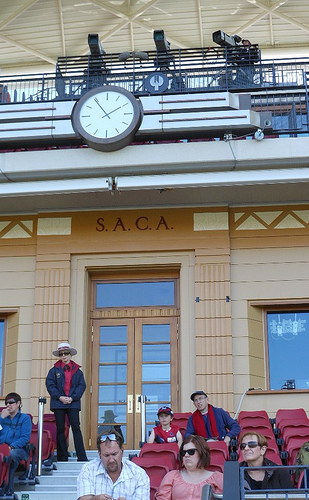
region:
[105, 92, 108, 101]
black line representing number on clock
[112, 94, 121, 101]
black line representing number on clock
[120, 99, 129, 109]
black line representing number on clock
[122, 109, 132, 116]
black line representing number on clock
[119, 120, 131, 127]
black line representing number on clock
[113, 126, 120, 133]
black line representing number on clock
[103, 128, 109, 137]
black line representing number on clock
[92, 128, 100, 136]
black line representing number on clock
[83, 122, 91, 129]
black line representing number on clock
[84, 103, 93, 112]
black line representing number on clock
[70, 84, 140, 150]
clock with a white face and brown numbers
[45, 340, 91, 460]
woman wearing a white hat and sunglasses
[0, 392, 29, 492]
man wearing sunglasses and a blue jacket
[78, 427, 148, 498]
man with sunglasses on his head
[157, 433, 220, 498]
woman with a pink shirt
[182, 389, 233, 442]
man wearing a blue jacket and red scarf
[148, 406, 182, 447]
child wearing a hat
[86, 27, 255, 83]
three television cameras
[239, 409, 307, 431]
red seats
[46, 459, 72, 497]
stairs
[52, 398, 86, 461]
THE WOMAN IS WEARING BLACK PANTS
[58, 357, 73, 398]
THE WOMAN IS WEARING A RED SHIRT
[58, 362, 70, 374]
THE WOMAN IS WEARING A BLACK TIE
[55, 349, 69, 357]
THE WOMAN IS WEARING DARK SUNGLASSES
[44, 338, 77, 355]
THE WOMAN IS WEARING A HAT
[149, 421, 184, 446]
THE KID IS WEARING A RED SHIRT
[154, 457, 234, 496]
THE WOMAN IS WEARING A PINK SHIRT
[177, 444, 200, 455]
THE WOMAN IS WEARING SUNGLASSES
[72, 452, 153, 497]
THE MAN IS WEARING A WHITE SHIRT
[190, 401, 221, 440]
THE MAN IS WEARING A RED SCARF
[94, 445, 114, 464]
eye of a person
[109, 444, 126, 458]
eye of a person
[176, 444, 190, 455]
eye of a person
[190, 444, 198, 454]
eye of a person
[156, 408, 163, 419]
eye of a person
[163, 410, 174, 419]
eye of a person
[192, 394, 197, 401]
eye of a person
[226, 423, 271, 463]
head of a person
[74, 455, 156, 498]
Man wearing a shirt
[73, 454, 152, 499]
Man is wearing a white shirt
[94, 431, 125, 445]
Sunglasses on man's head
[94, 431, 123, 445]
Sunglasses are on man's head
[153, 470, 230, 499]
Woman wearing a shirt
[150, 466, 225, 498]
Woman wearing a pink shirt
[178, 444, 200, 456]
Woman wearing black sunglasses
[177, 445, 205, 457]
Woman is wearing black sunglasses